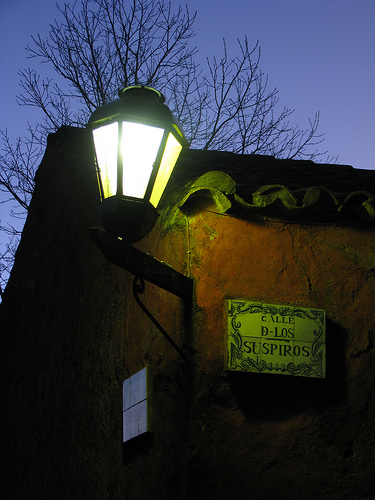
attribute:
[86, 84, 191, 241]
light — white, bright yellow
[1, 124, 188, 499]
wall — dark brown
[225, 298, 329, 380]
sign — black, white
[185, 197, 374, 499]
wall — dark brown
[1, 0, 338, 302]
tree — bare, deciduous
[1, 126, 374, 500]
building — dark brown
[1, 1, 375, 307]
sky — dark blue, clear, blue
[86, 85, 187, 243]
frame — black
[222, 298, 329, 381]
tile — bordered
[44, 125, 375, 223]
shingles — roof shingles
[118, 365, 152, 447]
window — lit